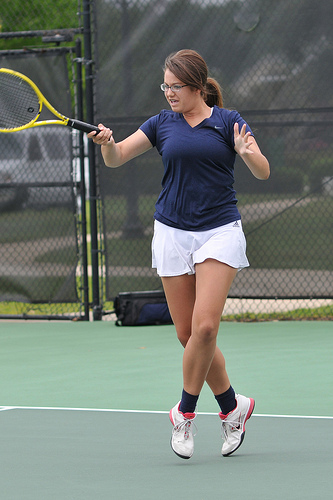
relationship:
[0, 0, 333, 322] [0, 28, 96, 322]
fence with gate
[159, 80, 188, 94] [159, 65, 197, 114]
glasses on face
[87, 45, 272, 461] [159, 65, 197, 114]
girl has face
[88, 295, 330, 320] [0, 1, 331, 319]
sidewalk outside of fence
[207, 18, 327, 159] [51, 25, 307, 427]
fence around court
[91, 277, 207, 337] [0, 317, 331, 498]
bag sitting on ground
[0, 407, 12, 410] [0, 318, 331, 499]
line marked on court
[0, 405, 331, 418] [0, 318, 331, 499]
line marked on court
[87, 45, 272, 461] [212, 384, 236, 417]
girl wearing sock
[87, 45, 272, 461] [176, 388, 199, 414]
girl wearing sock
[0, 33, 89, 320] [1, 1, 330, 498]
gate for fence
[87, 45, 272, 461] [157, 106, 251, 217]
girl wearing shirt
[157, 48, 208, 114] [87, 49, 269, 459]
head of girl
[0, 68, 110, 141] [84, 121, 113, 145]
racket held in hand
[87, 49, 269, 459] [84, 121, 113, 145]
girl has hand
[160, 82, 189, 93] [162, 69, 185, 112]
glasses worn on face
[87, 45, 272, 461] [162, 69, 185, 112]
girl has face